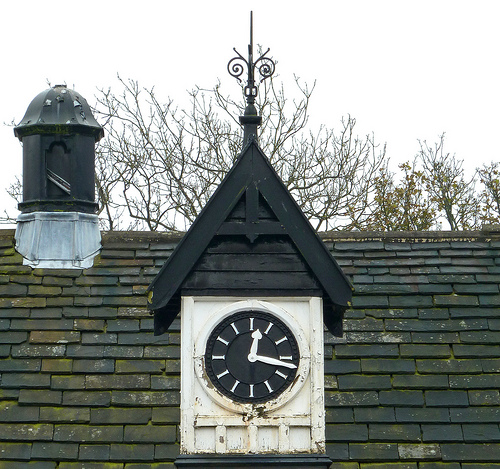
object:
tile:
[41, 359, 73, 374]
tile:
[106, 318, 140, 333]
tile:
[73, 318, 105, 332]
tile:
[81, 333, 118, 344]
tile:
[77, 442, 153, 463]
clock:
[200, 307, 298, 407]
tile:
[368, 422, 422, 442]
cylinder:
[13, 80, 107, 265]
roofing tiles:
[397, 249, 438, 257]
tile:
[123, 423, 177, 443]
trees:
[397, 157, 435, 231]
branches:
[289, 69, 319, 101]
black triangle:
[143, 135, 353, 337]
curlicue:
[224, 41, 276, 83]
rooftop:
[0, 220, 491, 469]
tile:
[90, 407, 150, 426]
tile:
[62, 390, 111, 407]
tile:
[85, 372, 150, 391]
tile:
[70, 345, 143, 360]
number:
[263, 380, 276, 395]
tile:
[388, 295, 433, 308]